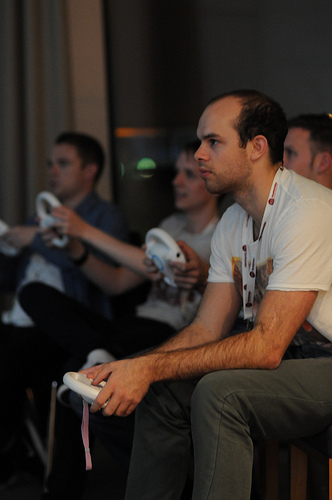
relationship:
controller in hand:
[137, 224, 199, 296] [170, 235, 209, 299]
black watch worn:
[78, 245, 90, 270] [62, 243, 100, 273]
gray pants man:
[129, 342, 330, 499] [123, 90, 331, 496]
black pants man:
[15, 275, 187, 361] [109, 138, 213, 378]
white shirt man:
[170, 192, 328, 297] [123, 90, 331, 496]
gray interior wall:
[220, 17, 253, 47] [197, 2, 330, 102]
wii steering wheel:
[144, 225, 185, 287] [140, 226, 193, 291]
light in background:
[126, 151, 165, 187] [98, 125, 188, 197]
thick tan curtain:
[62, 4, 113, 133] [7, 3, 108, 147]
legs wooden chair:
[285, 444, 310, 497] [252, 429, 330, 500]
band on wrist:
[68, 248, 103, 270] [63, 244, 104, 275]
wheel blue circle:
[140, 226, 193, 291] [149, 252, 165, 276]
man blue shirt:
[123, 90, 331, 496] [18, 196, 131, 307]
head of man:
[189, 75, 294, 201] [123, 90, 331, 496]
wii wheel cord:
[144, 225, 185, 287] [77, 397, 98, 471]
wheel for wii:
[140, 226, 193, 291] [144, 225, 185, 287]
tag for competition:
[231, 244, 275, 316] [27, 105, 325, 348]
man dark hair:
[123, 90, 331, 496] [237, 90, 288, 141]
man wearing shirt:
[123, 90, 331, 496] [18, 196, 131, 307]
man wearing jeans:
[123, 90, 331, 496] [132, 345, 316, 472]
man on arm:
[123, 90, 331, 496] [257, 253, 305, 361]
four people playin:
[0, 87, 330, 500] [24, 109, 331, 389]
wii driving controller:
[144, 225, 185, 287] [144, 228, 186, 288]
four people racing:
[34, 87, 330, 324] [35, 189, 195, 287]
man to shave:
[123, 90, 331, 496] [219, 153, 266, 199]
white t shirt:
[170, 192, 328, 297] [209, 171, 330, 347]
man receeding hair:
[123, 90, 331, 496] [237, 90, 288, 141]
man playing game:
[123, 90, 331, 496] [51, 359, 107, 393]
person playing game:
[156, 77, 330, 337] [51, 359, 107, 393]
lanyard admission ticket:
[233, 216, 263, 323] [234, 318, 261, 340]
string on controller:
[77, 396, 100, 481] [137, 224, 199, 296]